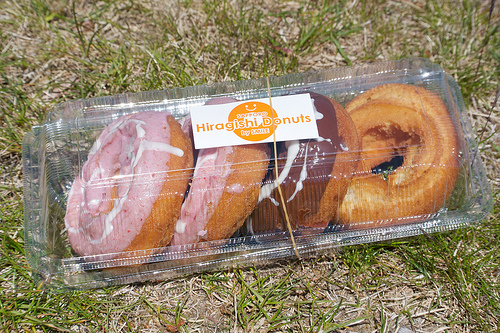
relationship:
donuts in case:
[65, 84, 455, 265] [21, 58, 491, 290]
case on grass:
[21, 58, 491, 290] [2, 0, 496, 329]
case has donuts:
[21, 58, 491, 290] [65, 84, 455, 265]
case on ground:
[21, 58, 491, 290] [14, 10, 214, 62]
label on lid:
[190, 92, 320, 150] [17, 60, 470, 225]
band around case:
[267, 140, 288, 197] [21, 58, 491, 290]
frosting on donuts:
[239, 91, 339, 239] [68, 90, 457, 250]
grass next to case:
[27, 291, 93, 313] [21, 58, 491, 290]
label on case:
[190, 92, 320, 150] [21, 58, 491, 290]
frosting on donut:
[239, 91, 339, 239] [258, 90, 358, 232]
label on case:
[190, 90, 320, 160] [21, 58, 491, 290]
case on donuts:
[18, 65, 497, 296] [68, 90, 457, 250]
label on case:
[190, 92, 320, 150] [22, 55, 489, 275]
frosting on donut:
[260, 202, 299, 232] [249, 90, 361, 241]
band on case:
[261, 141, 283, 188] [21, 58, 491, 290]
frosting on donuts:
[239, 91, 339, 239] [252, 87, 359, 250]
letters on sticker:
[196, 114, 311, 133] [189, 90, 325, 147]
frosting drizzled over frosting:
[62, 115, 185, 245] [64, 118, 183, 245]